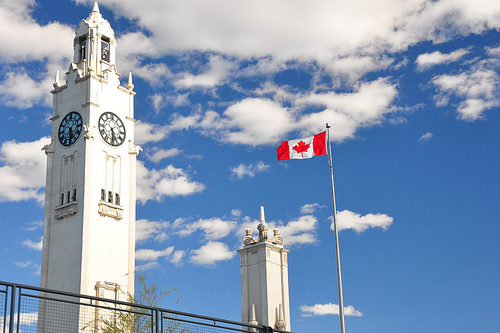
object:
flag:
[275, 128, 329, 161]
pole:
[325, 122, 348, 332]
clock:
[98, 111, 127, 148]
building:
[39, 3, 142, 332]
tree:
[82, 273, 188, 332]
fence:
[1, 276, 299, 332]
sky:
[0, 0, 499, 332]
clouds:
[170, 78, 400, 151]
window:
[99, 36, 113, 65]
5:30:
[110, 128, 118, 145]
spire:
[72, 2, 117, 77]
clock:
[58, 111, 84, 146]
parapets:
[51, 59, 134, 92]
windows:
[99, 150, 124, 220]